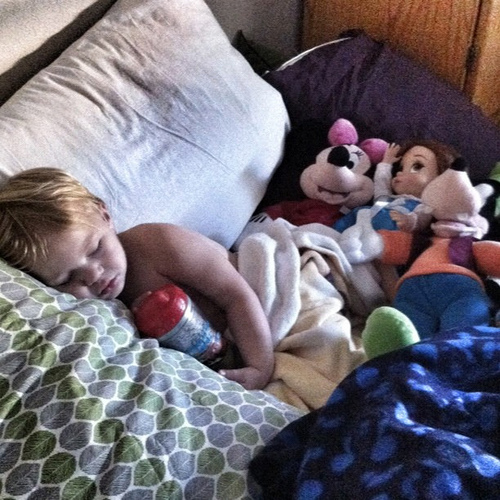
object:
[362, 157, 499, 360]
animal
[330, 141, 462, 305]
character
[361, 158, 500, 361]
character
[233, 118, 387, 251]
character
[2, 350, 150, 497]
design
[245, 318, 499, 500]
sheet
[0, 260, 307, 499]
pillow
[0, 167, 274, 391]
child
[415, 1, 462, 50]
wall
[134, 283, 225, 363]
bottle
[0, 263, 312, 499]
pillow case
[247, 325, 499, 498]
blanket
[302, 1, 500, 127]
cabinet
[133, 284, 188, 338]
lid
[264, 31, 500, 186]
pillow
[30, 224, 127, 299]
face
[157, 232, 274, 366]
arm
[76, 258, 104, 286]
nose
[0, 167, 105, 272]
hair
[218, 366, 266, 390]
hand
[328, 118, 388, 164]
bow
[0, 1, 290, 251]
pillow